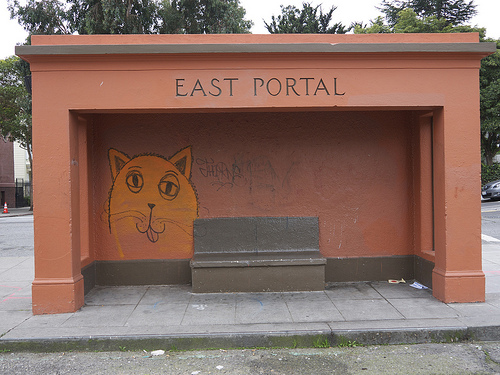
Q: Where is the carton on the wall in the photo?
A: Beside the wooden bench.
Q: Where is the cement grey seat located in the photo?
A: On grey payment.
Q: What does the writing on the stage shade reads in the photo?
A: EAST PORTAL.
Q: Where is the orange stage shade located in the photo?
A: On grey pavement.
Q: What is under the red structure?
A: Bench.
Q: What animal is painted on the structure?
A: Cat.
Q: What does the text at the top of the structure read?
A: East Portal.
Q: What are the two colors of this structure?
A: Red and brown.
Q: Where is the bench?
A: Under the structure.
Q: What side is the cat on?
A: Left.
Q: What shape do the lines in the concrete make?
A: Rectangles.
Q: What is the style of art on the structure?
A: Graffiti.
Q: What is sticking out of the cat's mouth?
A: Tongue.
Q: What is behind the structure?
A: Trees.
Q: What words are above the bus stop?
A: East Portal.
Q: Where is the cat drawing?
A: On the wall.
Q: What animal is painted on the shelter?
A: A cat.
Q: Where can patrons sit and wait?
A: On the concrete bench.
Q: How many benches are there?
A: One.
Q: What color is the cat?
A: Orange.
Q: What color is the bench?
A: Brown.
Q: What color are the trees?
A: Green.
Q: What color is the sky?
A: Gray.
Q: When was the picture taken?
A: Daytime.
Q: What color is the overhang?
A: Red.